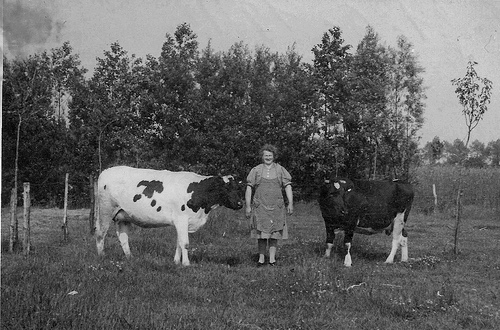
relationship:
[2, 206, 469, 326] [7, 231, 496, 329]
field with short grass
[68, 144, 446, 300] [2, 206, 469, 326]
two cows standing in field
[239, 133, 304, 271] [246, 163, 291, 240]
blonde fat woman in milk maids outfit